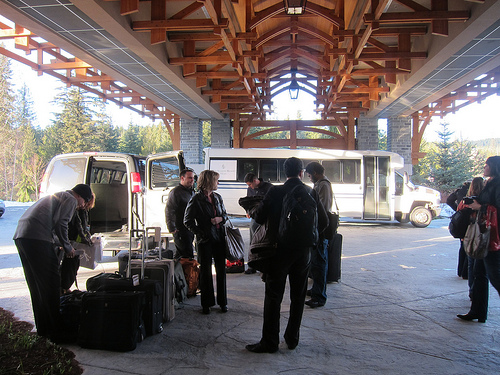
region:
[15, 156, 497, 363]
people waiting for rides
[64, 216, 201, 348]
luggage of people waiting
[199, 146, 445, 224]
blue and white shuttle bus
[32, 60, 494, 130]
overhead structure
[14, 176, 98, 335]
man wearing gray shirt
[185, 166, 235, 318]
woman with her head turned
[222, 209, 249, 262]
purse of woman with her head turned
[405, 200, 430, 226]
front tire of shuttle bus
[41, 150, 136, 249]
back of van with door open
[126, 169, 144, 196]
red taillight of van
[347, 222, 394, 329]
part of a floor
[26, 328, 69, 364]
part of a plant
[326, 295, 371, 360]
part of a floor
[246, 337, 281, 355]
edge of a shore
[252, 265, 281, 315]
part of a trouser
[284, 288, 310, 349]
edge of a trouser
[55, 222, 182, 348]
row of luggage sitting on ground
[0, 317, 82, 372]
bush with green leaves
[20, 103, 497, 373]
group of people standing beside vehicles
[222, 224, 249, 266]
grey bag on side of person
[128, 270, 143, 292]
white tag on top of luggage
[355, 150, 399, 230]
large doors on side of shuttle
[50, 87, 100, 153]
trees with green leaves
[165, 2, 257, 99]
brown metal ceiling rafters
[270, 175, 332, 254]
black backpack on back of man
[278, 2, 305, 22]
light on ceiling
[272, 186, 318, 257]
person wearing a backpack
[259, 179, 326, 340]
the person is standing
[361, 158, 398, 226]
the door on the bus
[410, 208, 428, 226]
front tire on the bus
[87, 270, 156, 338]
luggage on the ground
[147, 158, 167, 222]
the back door of the van open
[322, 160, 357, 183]
windows on the bus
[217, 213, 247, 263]
women carrying a bag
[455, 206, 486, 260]
women carrying many bags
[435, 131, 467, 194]
a green tree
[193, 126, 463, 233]
bus parked at entrance of building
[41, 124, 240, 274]
van door open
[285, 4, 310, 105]
lights in the ceiling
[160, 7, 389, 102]
beams exposed on the ceiling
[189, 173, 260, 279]
woman holding a bag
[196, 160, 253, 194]
bus has two blue stripes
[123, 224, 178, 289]
handles of the suitcare are up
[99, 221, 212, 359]
luggage sitting on the ground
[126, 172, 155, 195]
taillight of the van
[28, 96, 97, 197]
pine trees in front of building